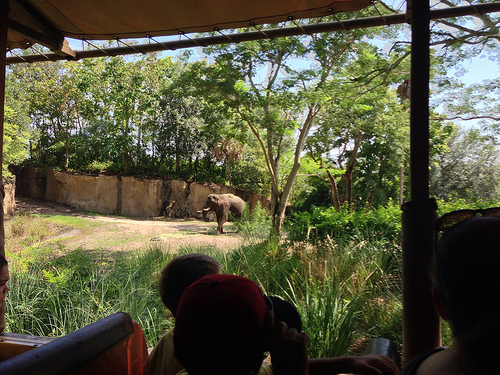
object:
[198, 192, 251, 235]
elephant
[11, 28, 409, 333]
exhibit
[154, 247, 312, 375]
children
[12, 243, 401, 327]
grass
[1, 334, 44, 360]
fence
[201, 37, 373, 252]
tree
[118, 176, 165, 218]
stones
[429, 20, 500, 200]
sky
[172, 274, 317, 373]
boy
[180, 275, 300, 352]
cap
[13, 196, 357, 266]
ground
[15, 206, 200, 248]
dirt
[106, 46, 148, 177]
trees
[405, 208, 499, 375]
person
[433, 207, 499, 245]
sunglasses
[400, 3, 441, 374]
pole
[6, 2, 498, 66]
canopy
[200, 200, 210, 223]
trunk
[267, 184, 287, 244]
trunk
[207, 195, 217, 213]
head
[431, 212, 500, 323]
head